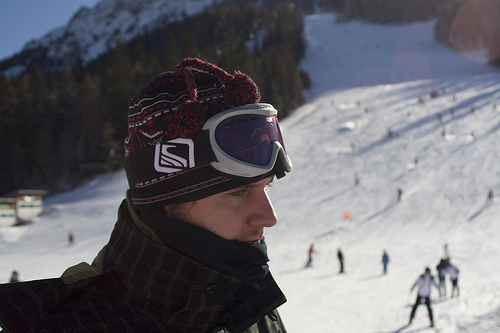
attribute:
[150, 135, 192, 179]
logo — white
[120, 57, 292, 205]
hat — red, black